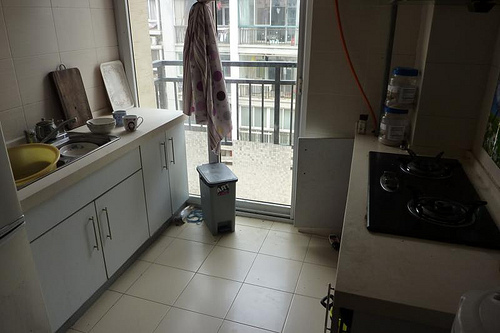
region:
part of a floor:
[226, 270, 256, 320]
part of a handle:
[95, 212, 118, 247]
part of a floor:
[240, 260, 264, 287]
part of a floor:
[246, 218, 256, 228]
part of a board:
[112, 212, 148, 281]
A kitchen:
[2, 0, 498, 327]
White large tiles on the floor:
[40, 201, 346, 328]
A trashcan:
[197, 162, 238, 236]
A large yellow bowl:
[8, 142, 59, 185]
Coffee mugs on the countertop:
[112, 108, 144, 134]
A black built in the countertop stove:
[361, 145, 498, 261]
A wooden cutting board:
[49, 65, 95, 128]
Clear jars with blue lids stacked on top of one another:
[376, 65, 420, 147]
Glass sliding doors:
[146, 2, 302, 221]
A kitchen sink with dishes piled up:
[2, 116, 119, 193]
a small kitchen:
[6, 5, 496, 326]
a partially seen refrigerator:
[1, 123, 54, 331]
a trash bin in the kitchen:
[193, 160, 243, 237]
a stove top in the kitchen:
[363, 140, 499, 248]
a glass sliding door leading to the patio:
[143, 1, 295, 224]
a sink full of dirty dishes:
[8, 114, 123, 190]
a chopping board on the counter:
[48, 60, 95, 133]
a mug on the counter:
[120, 113, 145, 133]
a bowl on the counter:
[83, 113, 117, 136]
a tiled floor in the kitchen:
[146, 243, 320, 332]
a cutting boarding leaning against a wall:
[48, 66, 97, 129]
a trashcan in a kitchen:
[196, 160, 241, 240]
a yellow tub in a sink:
[7, 139, 58, 188]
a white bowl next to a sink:
[85, 114, 120, 133]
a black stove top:
[360, 145, 498, 251]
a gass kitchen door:
[143, 0, 301, 211]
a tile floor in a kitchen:
[64, 205, 341, 331]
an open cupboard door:
[290, 133, 356, 239]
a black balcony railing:
[156, 58, 296, 144]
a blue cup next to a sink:
[113, 108, 127, 125]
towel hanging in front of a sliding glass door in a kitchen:
[181, 0, 232, 155]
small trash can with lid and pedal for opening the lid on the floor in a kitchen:
[196, 160, 238, 237]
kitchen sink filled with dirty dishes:
[5, 115, 119, 190]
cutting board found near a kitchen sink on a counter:
[46, 65, 92, 128]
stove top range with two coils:
[369, 144, 494, 246]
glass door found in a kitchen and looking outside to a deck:
[133, 3, 308, 224]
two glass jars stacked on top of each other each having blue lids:
[376, 66, 418, 148]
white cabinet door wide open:
[291, 133, 352, 233]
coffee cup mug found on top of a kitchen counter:
[121, 113, 142, 133]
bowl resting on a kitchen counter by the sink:
[87, 117, 117, 134]